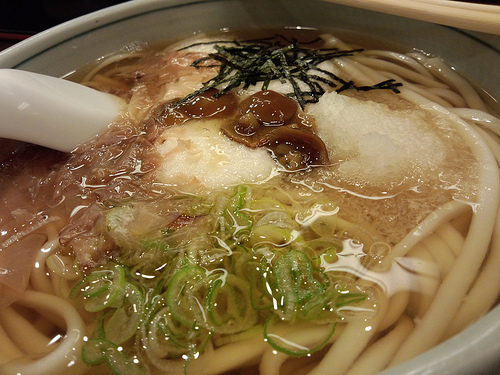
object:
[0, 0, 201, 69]
edge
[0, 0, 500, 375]
bowl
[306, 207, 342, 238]
onions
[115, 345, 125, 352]
spots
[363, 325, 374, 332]
spots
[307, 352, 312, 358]
spots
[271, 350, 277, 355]
spots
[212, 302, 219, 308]
spots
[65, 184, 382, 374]
vegetables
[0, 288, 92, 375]
circle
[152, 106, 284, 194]
dumpling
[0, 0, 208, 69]
trim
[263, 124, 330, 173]
mushroom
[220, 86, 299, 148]
mushroom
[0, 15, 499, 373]
soup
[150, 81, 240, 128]
mushroom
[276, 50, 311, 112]
spices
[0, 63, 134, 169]
handle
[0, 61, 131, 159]
spoon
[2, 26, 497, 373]
food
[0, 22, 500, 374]
broth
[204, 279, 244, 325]
green onions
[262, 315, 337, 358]
onion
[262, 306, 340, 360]
onion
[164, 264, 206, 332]
onion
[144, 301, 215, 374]
onion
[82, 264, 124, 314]
onion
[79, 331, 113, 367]
onion